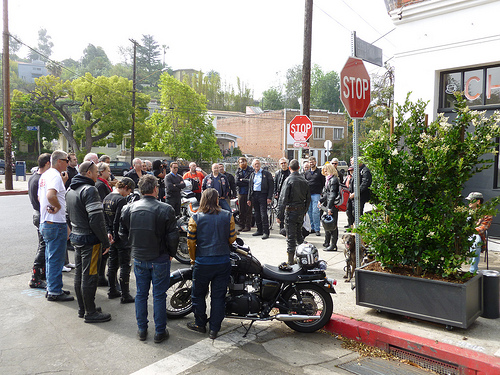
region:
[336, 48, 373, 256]
a red sign on the corner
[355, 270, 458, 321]
a gray wooden planter box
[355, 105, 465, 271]
a small green shrub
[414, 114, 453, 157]
white blooms on the shrub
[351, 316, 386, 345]
red paint on the curb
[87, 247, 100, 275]
a yellow stripe on pants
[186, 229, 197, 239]
blue stripes on a sleeve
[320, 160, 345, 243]
a woman holding a helmet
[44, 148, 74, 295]
a man wearing white t-shirt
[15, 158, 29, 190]
a blue mailbox across the street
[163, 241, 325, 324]
A black motorcycle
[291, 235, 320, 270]
A motorcycle helmet on the motorcycle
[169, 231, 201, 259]
the wheel of a motorcycle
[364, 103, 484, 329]
A potted bush on the sidewalk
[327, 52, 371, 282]
A stop sign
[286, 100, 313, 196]
A stop sign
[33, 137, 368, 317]
A large group of people in a circle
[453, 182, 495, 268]
A man in a flannel shirt sitting down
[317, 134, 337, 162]
The back of a stop sign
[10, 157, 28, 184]
A mail drop off box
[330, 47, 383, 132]
A red stop sign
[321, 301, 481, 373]
Red curb of a sidewalk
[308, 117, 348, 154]
Windows on a brown building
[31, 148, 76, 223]
Man wearing a white shirt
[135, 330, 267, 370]
Thick white line on the street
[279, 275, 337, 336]
Round tire on a motorcycle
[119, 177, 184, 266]
Man wearing a black leather jacket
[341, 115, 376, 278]
Gray post holding up a stop sign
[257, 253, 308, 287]
Black leather seat on a motorbike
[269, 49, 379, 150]
Two red and white stop signs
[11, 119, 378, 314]
a bunch of bikers gathered on a corner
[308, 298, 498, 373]
red paint on a curb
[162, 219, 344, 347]
a black motorcycle parked at the curb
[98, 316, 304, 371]
thick white line on road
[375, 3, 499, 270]
part of a white building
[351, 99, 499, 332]
A gray planter box with large plant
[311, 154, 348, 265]
a blond haired woman holding helmet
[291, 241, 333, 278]
black helmet on back of motorcycle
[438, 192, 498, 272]
a man sitting in a chair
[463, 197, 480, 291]
man siting on bench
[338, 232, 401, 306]
dog is by the STOP sign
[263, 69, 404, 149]
two stop signs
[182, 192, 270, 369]
woman standing next to motorcycle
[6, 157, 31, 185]
mailbox next to street sign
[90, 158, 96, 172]
man has sunglasses on his head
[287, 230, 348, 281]
helmet on the motorcycle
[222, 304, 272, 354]
motorcycle standing on kickstand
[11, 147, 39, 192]
mailbox is blue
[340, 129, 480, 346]
box with plant in front of STOP sign